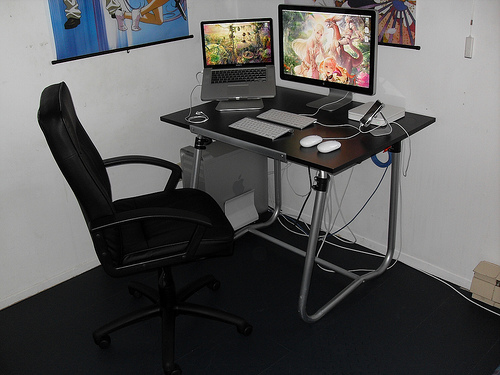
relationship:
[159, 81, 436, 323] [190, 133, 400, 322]
desk has legs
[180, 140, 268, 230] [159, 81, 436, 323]
apple computer next to desk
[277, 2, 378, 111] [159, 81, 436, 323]
imac on desk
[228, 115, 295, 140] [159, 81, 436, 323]
keyboard on desk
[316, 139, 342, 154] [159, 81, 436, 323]
mouse on desk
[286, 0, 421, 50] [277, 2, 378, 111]
poster behind imac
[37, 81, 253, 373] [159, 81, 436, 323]
chair in front of desk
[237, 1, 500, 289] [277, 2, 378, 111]
wall behind imac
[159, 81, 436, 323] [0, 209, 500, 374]
desk on floor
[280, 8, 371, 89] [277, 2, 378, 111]
screen on imac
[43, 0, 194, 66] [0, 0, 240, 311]
poster on wall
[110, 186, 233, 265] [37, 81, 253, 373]
seat on chair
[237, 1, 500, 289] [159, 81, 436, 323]
wall behind desk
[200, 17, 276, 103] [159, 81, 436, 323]
macbook on desk